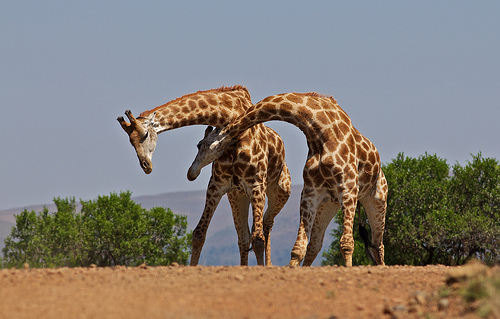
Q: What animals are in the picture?
A: Giraffes.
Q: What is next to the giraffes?
A: Green tree.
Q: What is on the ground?
A: Brown dirt.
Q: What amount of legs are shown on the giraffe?
A: Four.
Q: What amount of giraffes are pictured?
A: Two.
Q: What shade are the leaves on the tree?
A: Green.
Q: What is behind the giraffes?
A: Trees.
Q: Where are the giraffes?
A: In the field.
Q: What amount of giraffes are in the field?
A: Two.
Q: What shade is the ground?
A: Dirt.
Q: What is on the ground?
A: Brown dirt.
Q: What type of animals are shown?
A: Giraffes.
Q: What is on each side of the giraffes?
A: Bushes.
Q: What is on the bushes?
A: Leaves.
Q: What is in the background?
A: Mountains.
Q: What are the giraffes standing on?
A: Dirt.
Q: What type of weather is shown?
A: Overcast.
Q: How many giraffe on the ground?
A: Two.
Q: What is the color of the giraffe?
A: Brown.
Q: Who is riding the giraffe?
A: No one.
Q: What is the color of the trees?
A: Green.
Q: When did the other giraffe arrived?
A: Earlier.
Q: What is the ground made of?
A: Soil.